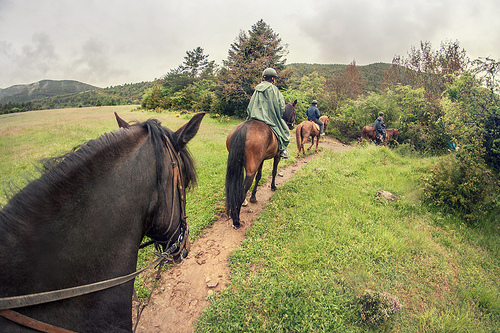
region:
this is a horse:
[14, 71, 230, 331]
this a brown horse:
[219, 77, 319, 222]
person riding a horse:
[206, 31, 323, 225]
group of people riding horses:
[18, 52, 445, 329]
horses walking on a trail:
[8, 59, 405, 309]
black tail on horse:
[209, 94, 260, 246]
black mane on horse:
[3, 88, 163, 306]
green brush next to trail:
[146, 45, 461, 164]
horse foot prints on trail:
[166, 199, 239, 299]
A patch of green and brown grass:
[305, 195, 450, 305]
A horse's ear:
[177, 108, 207, 140]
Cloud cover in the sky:
[25, 25, 147, 74]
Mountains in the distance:
[12, 68, 90, 114]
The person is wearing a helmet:
[375, 109, 388, 121]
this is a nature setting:
[16, 19, 479, 290]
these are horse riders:
[114, 59, 349, 222]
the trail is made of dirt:
[181, 226, 239, 317]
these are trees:
[162, 38, 275, 114]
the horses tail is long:
[219, 126, 251, 210]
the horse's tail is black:
[214, 141, 251, 216]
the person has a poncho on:
[235, 80, 290, 134]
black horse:
[10, 95, 200, 310]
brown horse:
[217, 121, 309, 201]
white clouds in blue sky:
[328, 21, 378, 46]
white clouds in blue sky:
[394, 12, 432, 53]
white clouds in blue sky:
[330, 15, 361, 40]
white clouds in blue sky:
[60, 29, 125, 60]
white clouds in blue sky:
[22, 18, 62, 58]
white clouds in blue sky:
[70, 12, 108, 43]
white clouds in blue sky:
[108, 28, 148, 66]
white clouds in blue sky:
[155, 22, 225, 50]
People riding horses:
[10, 2, 484, 317]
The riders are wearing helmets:
[238, 58, 472, 160]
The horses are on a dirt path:
[35, 26, 476, 298]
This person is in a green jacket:
[245, 60, 297, 159]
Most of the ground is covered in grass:
[25, 82, 462, 314]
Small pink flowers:
[350, 285, 407, 325]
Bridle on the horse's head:
[0, 101, 208, 300]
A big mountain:
[0, 68, 102, 106]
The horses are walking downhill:
[297, 88, 453, 165]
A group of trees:
[165, 37, 321, 108]